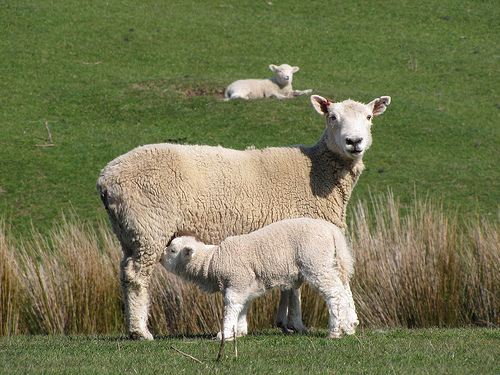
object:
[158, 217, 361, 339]
lamb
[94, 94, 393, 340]
sheep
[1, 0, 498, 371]
field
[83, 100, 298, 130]
ground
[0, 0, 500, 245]
green field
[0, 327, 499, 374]
green field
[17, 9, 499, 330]
grass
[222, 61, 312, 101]
lamb